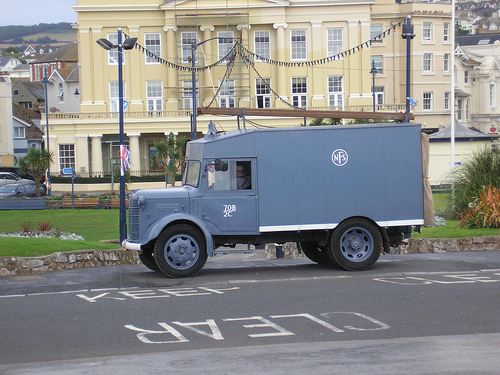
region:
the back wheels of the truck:
[326, 215, 386, 273]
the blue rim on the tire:
[165, 231, 199, 269]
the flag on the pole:
[116, 137, 131, 180]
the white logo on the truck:
[325, 144, 355, 171]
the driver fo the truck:
[226, 161, 247, 196]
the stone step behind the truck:
[426, 234, 498, 256]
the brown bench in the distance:
[51, 192, 113, 207]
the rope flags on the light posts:
[127, 23, 407, 94]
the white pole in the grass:
[444, 0, 466, 218]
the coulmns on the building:
[75, 20, 105, 116]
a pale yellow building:
[39, 0, 498, 195]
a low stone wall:
[0, 235, 494, 275]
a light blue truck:
[120, 106, 424, 278]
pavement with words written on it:
[0, 248, 498, 374]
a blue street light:
[92, 28, 137, 248]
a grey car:
[0, 178, 48, 199]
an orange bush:
[452, 179, 498, 231]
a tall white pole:
[449, 0, 456, 220]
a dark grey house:
[11, 78, 46, 115]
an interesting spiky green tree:
[150, 130, 190, 185]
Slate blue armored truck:
[125, 120, 427, 270]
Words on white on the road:
[70, 265, 499, 348]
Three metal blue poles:
[111, 13, 420, 246]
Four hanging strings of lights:
[122, 18, 408, 113]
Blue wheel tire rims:
[160, 233, 200, 270]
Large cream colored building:
[39, 0, 496, 197]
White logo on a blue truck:
[329, 143, 349, 172]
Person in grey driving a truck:
[221, 160, 251, 191]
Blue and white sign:
[60, 163, 75, 177]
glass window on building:
[106, 30, 123, 62]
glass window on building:
[144, 30, 162, 62]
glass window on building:
[181, 30, 197, 62]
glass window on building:
[215, 29, 235, 62]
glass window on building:
[253, 26, 270, 62]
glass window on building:
[328, 25, 343, 58]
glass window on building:
[108, 78, 125, 110]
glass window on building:
[145, 80, 162, 117]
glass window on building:
[254, 75, 271, 107]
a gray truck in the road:
[130, 113, 436, 283]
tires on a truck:
[153, 223, 393, 268]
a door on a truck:
[202, 155, 262, 237]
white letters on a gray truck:
[329, 146, 349, 168]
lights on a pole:
[92, 31, 137, 258]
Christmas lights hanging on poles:
[117, 18, 418, 100]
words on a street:
[77, 279, 393, 347]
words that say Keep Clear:
[70, 276, 388, 348]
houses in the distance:
[4, 39, 79, 188]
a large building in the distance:
[37, 9, 481, 174]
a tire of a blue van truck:
[146, 220, 208, 277]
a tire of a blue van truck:
[336, 224, 382, 270]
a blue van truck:
[96, 110, 454, 279]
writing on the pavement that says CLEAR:
[94, 305, 408, 346]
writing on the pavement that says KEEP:
[64, 278, 242, 304]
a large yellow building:
[31, 1, 467, 120]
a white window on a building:
[138, 74, 168, 116]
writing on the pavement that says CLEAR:
[287, 26, 313, 65]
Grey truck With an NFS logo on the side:
[123, 120, 423, 270]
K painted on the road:
[75, 272, 123, 309]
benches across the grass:
[0, 191, 141, 209]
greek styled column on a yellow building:
[163, 20, 178, 113]